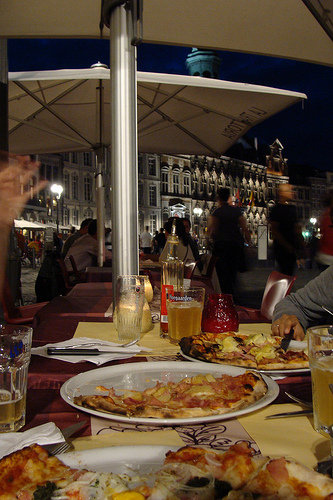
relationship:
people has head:
[158, 216, 203, 274] [164, 215, 185, 239]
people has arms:
[158, 216, 203, 274] [159, 238, 174, 264]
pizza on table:
[66, 367, 269, 418] [2, 315, 331, 497]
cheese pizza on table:
[19, 465, 316, 493] [2, 315, 331, 497]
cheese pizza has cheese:
[19, 465, 316, 493] [78, 475, 118, 495]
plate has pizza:
[70, 364, 219, 389] [66, 367, 269, 418]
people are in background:
[59, 214, 203, 274] [13, 158, 325, 266]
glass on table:
[111, 274, 147, 347] [2, 315, 331, 497]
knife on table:
[44, 343, 152, 359] [2, 315, 331, 497]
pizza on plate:
[66, 367, 269, 418] [70, 364, 219, 389]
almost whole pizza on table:
[179, 328, 317, 367] [2, 315, 331, 497]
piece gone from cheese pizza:
[51, 440, 167, 478] [19, 465, 316, 493]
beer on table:
[154, 279, 208, 341] [2, 315, 331, 497]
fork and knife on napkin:
[46, 340, 145, 357] [29, 335, 157, 367]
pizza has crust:
[66, 367, 269, 418] [79, 398, 165, 421]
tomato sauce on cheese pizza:
[4, 461, 20, 495] [19, 465, 316, 493]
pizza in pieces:
[66, 367, 269, 418] [96, 384, 158, 414]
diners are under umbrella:
[52, 214, 208, 270] [6, 62, 320, 161]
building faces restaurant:
[156, 160, 282, 233] [2, 156, 332, 498]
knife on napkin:
[44, 343, 152, 359] [29, 335, 157, 367]